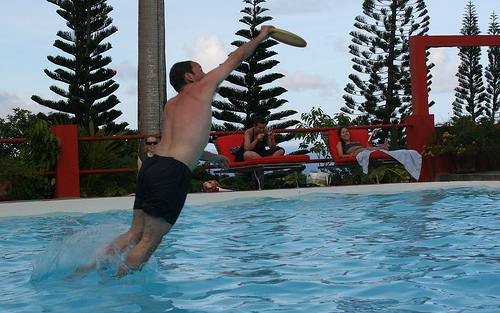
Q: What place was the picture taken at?
A: It was taken at the swimming pool.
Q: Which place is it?
A: It is a swimming pool.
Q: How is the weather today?
A: It is cloudy.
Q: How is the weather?
A: It is cloudy.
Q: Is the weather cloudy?
A: Yes, it is cloudy.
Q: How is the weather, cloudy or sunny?
A: It is cloudy.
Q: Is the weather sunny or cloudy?
A: It is cloudy.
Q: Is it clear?
A: No, it is cloudy.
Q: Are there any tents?
A: No, there are no tents.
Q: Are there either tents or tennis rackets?
A: No, there are no tents or tennis rackets.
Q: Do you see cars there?
A: No, there are no cars.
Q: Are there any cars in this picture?
A: No, there are no cars.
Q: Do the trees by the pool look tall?
A: Yes, the trees are tall.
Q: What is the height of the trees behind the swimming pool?
A: The trees are tall.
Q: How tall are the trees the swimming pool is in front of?
A: The trees are tall.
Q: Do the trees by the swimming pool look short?
A: No, the trees are tall.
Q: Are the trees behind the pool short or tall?
A: The trees are tall.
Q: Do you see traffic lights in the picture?
A: No, there are no traffic lights.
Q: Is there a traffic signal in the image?
A: No, there are no traffic lights.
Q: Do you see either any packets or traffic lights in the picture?
A: No, there are no traffic lights or packets.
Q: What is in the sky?
A: The clouds are in the sky.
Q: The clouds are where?
A: The clouds are in the sky.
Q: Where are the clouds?
A: The clouds are in the sky.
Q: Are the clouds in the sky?
A: Yes, the clouds are in the sky.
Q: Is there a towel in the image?
A: Yes, there is a towel.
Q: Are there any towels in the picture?
A: Yes, there is a towel.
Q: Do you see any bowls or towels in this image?
A: Yes, there is a towel.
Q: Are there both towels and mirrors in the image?
A: No, there is a towel but no mirrors.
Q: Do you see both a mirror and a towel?
A: No, there is a towel but no mirrors.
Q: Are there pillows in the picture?
A: No, there are no pillows.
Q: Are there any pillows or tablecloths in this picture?
A: No, there are no pillows or tablecloths.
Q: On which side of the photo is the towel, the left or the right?
A: The towel is on the right of the image.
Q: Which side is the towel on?
A: The towel is on the right of the image.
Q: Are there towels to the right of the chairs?
A: Yes, there is a towel to the right of the chairs.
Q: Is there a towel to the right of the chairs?
A: Yes, there is a towel to the right of the chairs.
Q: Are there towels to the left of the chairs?
A: No, the towel is to the right of the chairs.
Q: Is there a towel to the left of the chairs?
A: No, the towel is to the right of the chairs.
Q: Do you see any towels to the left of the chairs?
A: No, the towel is to the right of the chairs.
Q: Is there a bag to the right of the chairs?
A: No, there is a towel to the right of the chairs.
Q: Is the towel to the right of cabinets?
A: No, the towel is to the right of the chairs.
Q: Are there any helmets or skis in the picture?
A: No, there are no helmets or skis.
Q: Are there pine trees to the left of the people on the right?
A: Yes, there is a pine tree to the left of the people.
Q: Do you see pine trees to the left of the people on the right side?
A: Yes, there is a pine tree to the left of the people.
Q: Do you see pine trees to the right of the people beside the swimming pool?
A: No, the pine tree is to the left of the people.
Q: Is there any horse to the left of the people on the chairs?
A: No, there is a pine tree to the left of the people.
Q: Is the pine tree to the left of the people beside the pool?
A: Yes, the pine tree is to the left of the people.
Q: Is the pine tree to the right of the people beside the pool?
A: No, the pine tree is to the left of the people.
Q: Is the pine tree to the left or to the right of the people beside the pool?
A: The pine tree is to the left of the people.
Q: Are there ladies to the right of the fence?
A: Yes, there is a lady to the right of the fence.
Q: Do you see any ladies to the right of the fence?
A: Yes, there is a lady to the right of the fence.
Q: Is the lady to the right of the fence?
A: Yes, the lady is to the right of the fence.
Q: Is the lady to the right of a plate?
A: No, the lady is to the right of the fence.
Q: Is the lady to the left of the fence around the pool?
A: No, the lady is to the right of the fence.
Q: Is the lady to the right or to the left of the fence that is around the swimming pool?
A: The lady is to the right of the fence.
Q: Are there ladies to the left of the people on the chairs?
A: Yes, there is a lady to the left of the people.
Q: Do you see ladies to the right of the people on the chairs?
A: No, the lady is to the left of the people.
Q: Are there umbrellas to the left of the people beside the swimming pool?
A: No, there is a lady to the left of the people.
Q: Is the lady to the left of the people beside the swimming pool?
A: Yes, the lady is to the left of the people.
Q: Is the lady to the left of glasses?
A: No, the lady is to the left of the people.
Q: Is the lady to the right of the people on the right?
A: No, the lady is to the left of the people.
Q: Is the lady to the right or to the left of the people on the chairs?
A: The lady is to the left of the people.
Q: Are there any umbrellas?
A: No, there are no umbrellas.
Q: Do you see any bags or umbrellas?
A: No, there are no umbrellas or bags.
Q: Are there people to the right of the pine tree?
A: Yes, there are people to the right of the pine tree.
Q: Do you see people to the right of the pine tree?
A: Yes, there are people to the right of the pine tree.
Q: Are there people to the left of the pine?
A: No, the people are to the right of the pine.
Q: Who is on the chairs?
A: The people are on the chairs.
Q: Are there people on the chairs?
A: Yes, there are people on the chairs.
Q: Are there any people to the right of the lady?
A: Yes, there are people to the right of the lady.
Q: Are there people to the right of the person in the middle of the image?
A: Yes, there are people to the right of the lady.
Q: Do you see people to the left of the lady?
A: No, the people are to the right of the lady.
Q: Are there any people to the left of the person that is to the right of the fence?
A: No, the people are to the right of the lady.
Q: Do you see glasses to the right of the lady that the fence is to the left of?
A: No, there are people to the right of the lady.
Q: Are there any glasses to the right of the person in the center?
A: No, there are people to the right of the lady.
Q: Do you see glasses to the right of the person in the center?
A: No, there are people to the right of the lady.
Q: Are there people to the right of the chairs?
A: Yes, there are people to the right of the chairs.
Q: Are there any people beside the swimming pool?
A: Yes, there are people beside the swimming pool.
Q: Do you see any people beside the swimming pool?
A: Yes, there are people beside the swimming pool.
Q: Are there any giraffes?
A: No, there are no giraffes.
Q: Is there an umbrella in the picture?
A: No, there are no umbrellas.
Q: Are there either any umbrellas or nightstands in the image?
A: No, there are no umbrellas or nightstands.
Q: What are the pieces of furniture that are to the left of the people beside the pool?
A: The pieces of furniture are chairs.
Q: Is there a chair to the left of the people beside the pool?
A: Yes, there are chairs to the left of the people.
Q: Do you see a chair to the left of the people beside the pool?
A: Yes, there are chairs to the left of the people.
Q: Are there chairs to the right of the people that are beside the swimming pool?
A: No, the chairs are to the left of the people.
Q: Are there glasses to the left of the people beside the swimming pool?
A: No, there are chairs to the left of the people.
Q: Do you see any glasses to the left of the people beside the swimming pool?
A: No, there are chairs to the left of the people.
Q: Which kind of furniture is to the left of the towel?
A: The pieces of furniture are chairs.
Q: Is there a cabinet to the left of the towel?
A: No, there are chairs to the left of the towel.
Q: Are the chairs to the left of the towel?
A: Yes, the chairs are to the left of the towel.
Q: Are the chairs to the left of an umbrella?
A: No, the chairs are to the left of the towel.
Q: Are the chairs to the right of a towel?
A: No, the chairs are to the left of a towel.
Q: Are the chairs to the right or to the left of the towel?
A: The chairs are to the left of the towel.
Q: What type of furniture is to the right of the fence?
A: The pieces of furniture are chairs.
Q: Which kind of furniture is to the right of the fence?
A: The pieces of furniture are chairs.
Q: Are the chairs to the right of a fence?
A: Yes, the chairs are to the right of a fence.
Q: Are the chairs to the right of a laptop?
A: No, the chairs are to the right of a fence.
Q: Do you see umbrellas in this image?
A: No, there are no umbrellas.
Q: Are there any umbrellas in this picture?
A: No, there are no umbrellas.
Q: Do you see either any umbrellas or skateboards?
A: No, there are no umbrellas or skateboards.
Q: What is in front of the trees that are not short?
A: The pool is in front of the trees.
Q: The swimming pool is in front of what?
A: The swimming pool is in front of the trees.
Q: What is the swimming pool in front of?
A: The swimming pool is in front of the trees.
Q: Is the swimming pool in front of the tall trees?
A: Yes, the swimming pool is in front of the trees.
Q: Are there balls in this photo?
A: No, there are no balls.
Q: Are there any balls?
A: No, there are no balls.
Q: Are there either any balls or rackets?
A: No, there are no balls or rackets.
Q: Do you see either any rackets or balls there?
A: No, there are no balls or rackets.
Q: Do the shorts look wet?
A: Yes, the shorts are wet.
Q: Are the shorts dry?
A: No, the shorts are wet.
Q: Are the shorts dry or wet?
A: The shorts are wet.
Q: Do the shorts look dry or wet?
A: The shorts are wet.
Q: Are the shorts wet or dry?
A: The shorts are wet.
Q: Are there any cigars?
A: No, there are no cigars.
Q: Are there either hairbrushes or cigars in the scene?
A: No, there are no cigars or hairbrushes.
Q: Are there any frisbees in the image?
A: Yes, there is a frisbee.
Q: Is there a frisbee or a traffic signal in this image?
A: Yes, there is a frisbee.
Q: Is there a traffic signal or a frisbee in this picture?
A: Yes, there is a frisbee.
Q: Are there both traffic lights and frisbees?
A: No, there is a frisbee but no traffic lights.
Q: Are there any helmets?
A: No, there are no helmets.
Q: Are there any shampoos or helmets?
A: No, there are no helmets or shampoos.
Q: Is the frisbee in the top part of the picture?
A: Yes, the frisbee is in the top of the image.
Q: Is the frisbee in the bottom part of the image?
A: No, the frisbee is in the top of the image.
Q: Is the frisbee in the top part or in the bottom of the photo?
A: The frisbee is in the top of the image.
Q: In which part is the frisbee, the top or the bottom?
A: The frisbee is in the top of the image.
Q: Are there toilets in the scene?
A: No, there are no toilets.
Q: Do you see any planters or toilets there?
A: No, there are no toilets or planters.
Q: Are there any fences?
A: Yes, there is a fence.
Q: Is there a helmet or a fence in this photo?
A: Yes, there is a fence.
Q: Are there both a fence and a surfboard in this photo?
A: No, there is a fence but no surfboards.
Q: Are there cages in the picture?
A: No, there are no cages.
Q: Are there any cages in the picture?
A: No, there are no cages.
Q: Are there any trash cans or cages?
A: No, there are no cages or trash cans.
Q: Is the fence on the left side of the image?
A: Yes, the fence is on the left of the image.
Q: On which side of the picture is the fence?
A: The fence is on the left of the image.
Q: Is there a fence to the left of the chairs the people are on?
A: Yes, there is a fence to the left of the chairs.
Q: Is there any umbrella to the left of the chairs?
A: No, there is a fence to the left of the chairs.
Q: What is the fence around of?
A: The fence is around the swimming pool.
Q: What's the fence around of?
A: The fence is around the swimming pool.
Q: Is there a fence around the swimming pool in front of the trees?
A: Yes, there is a fence around the pool.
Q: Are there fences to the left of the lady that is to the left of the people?
A: Yes, there is a fence to the left of the lady.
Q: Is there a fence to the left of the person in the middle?
A: Yes, there is a fence to the left of the lady.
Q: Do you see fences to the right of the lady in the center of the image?
A: No, the fence is to the left of the lady.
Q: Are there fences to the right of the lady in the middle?
A: No, the fence is to the left of the lady.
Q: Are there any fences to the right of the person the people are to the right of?
A: No, the fence is to the left of the lady.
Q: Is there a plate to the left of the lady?
A: No, there is a fence to the left of the lady.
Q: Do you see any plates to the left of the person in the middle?
A: No, there is a fence to the left of the lady.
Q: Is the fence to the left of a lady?
A: Yes, the fence is to the left of a lady.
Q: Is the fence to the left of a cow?
A: No, the fence is to the left of a lady.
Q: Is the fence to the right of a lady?
A: No, the fence is to the left of a lady.